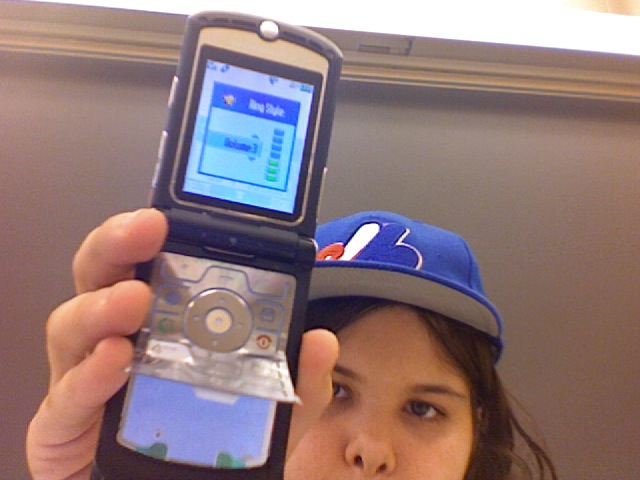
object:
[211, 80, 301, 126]
banner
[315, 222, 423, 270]
logo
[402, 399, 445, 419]
eye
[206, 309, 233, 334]
center button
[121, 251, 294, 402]
keyboard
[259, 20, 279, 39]
carrier emblem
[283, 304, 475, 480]
face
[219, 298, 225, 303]
arrow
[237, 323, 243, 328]
arrow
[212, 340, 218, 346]
arrow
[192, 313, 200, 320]
arrow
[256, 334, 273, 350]
button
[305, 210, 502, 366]
hat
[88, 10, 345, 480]
cellphone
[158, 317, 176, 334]
button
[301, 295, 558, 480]
hair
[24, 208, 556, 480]
child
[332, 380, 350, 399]
eye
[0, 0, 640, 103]
molding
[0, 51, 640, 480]
wall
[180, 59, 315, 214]
screen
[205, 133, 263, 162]
volume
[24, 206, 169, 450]
fingers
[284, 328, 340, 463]
thumb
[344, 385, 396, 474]
bridge